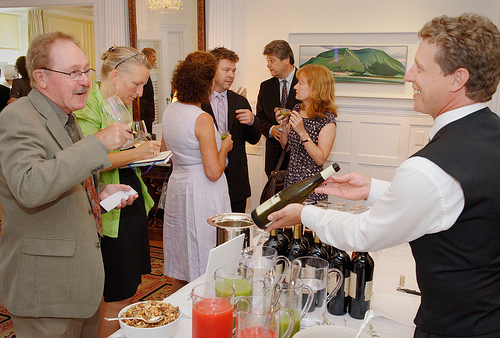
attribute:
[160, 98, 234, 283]
dress — white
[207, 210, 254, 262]
silver plate — big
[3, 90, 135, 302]
suit — brown 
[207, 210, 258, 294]
plate — big, silver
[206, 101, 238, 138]
tie — striped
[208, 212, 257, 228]
plate — silver, big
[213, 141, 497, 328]
plate — silver, big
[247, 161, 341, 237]
champagne — bottle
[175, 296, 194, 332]
plate — big, silver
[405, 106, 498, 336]
vest — black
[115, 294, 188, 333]
bowl — white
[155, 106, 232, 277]
dress — white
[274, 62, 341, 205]
woman — black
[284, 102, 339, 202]
dress — white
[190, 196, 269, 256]
plate — big, silver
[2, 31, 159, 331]
man/wine — sipping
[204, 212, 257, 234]
plate — big, silver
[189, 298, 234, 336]
drink — red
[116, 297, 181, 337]
bowl — white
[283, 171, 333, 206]
bottle — champagne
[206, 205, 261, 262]
plate — big, silver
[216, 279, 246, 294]
drink — green